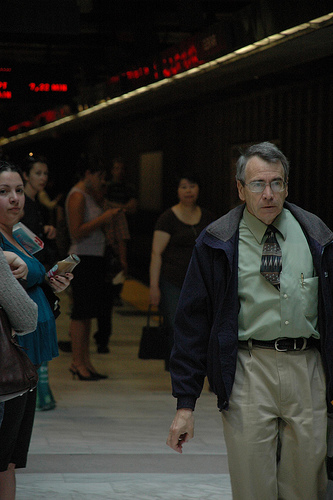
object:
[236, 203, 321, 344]
shirt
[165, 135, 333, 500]
man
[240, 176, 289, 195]
eyeglasses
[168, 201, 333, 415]
jacket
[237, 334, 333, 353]
belt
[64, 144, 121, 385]
woman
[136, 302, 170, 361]
purse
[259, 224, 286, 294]
necktie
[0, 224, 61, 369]
blouse